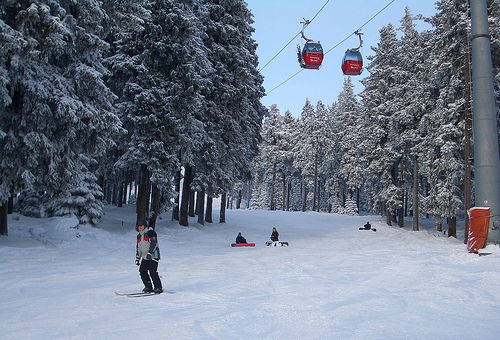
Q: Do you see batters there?
A: No, there are no batters.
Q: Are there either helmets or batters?
A: No, there are no batters or helmets.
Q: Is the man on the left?
A: Yes, the man is on the left of the image.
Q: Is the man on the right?
A: No, the man is on the left of the image.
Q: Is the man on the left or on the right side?
A: The man is on the left of the image.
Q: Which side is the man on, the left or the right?
A: The man is on the left of the image.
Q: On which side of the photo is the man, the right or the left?
A: The man is on the left of the image.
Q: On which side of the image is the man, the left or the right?
A: The man is on the left of the image.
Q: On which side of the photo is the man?
A: The man is on the left of the image.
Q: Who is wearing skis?
A: The man is wearing skis.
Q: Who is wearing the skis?
A: The man is wearing skis.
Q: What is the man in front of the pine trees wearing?
A: The man is wearing skis.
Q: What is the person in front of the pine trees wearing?
A: The man is wearing skis.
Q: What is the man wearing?
A: The man is wearing skis.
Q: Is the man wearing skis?
A: Yes, the man is wearing skis.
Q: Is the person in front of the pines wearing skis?
A: Yes, the man is wearing skis.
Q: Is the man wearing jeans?
A: No, the man is wearing skis.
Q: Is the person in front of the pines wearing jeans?
A: No, the man is wearing skis.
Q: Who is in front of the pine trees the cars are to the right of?
A: The man is in front of the pines.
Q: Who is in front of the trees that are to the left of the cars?
A: The man is in front of the pines.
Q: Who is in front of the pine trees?
A: The man is in front of the pines.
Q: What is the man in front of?
A: The man is in front of the pines.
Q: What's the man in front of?
A: The man is in front of the pines.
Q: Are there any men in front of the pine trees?
A: Yes, there is a man in front of the pine trees.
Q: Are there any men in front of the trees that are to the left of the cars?
A: Yes, there is a man in front of the pine trees.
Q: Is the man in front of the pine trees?
A: Yes, the man is in front of the pine trees.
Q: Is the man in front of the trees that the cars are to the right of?
A: Yes, the man is in front of the pine trees.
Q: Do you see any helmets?
A: No, there are no helmets.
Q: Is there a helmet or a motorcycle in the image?
A: No, there are no helmets or motorcycles.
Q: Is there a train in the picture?
A: No, there are no trains.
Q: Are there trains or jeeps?
A: No, there are no trains or jeeps.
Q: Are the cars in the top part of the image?
A: Yes, the cars are in the top of the image.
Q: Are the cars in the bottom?
A: No, the cars are in the top of the image.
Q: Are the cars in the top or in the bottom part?
A: The cars are in the top of the image.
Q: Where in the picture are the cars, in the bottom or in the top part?
A: The cars are in the top of the image.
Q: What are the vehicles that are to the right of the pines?
A: The vehicles are cars.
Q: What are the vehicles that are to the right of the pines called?
A: The vehicles are cars.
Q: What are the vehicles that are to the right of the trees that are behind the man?
A: The vehicles are cars.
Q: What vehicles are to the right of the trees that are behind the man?
A: The vehicles are cars.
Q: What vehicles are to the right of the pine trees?
A: The vehicles are cars.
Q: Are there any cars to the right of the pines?
A: Yes, there are cars to the right of the pines.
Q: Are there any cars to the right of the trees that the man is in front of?
A: Yes, there are cars to the right of the pines.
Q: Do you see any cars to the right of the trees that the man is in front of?
A: Yes, there are cars to the right of the pines.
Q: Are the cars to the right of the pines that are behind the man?
A: Yes, the cars are to the right of the pines.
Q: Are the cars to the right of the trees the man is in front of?
A: Yes, the cars are to the right of the pines.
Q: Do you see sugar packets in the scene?
A: No, there are no sugar packets.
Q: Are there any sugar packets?
A: No, there are no sugar packets.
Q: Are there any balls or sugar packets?
A: No, there are no sugar packets or balls.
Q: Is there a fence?
A: No, there are no fences.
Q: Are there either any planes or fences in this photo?
A: No, there are no fences or planes.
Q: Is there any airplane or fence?
A: No, there are no fences or airplanes.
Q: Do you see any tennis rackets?
A: No, there are no tennis rackets.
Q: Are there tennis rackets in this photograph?
A: No, there are no tennis rackets.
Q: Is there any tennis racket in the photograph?
A: No, there are no rackets.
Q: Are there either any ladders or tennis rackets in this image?
A: No, there are no tennis rackets or ladders.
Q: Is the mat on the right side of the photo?
A: Yes, the mat is on the right of the image.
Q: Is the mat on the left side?
A: No, the mat is on the right of the image.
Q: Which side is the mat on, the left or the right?
A: The mat is on the right of the image.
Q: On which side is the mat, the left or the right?
A: The mat is on the right of the image.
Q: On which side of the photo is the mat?
A: The mat is on the right of the image.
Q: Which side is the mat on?
A: The mat is on the right of the image.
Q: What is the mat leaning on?
A: The mat is leaning on the pole.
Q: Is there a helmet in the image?
A: No, there are no helmets.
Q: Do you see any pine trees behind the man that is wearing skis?
A: Yes, there are pine trees behind the man.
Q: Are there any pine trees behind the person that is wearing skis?
A: Yes, there are pine trees behind the man.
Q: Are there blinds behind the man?
A: No, there are pine trees behind the man.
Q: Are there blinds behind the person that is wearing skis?
A: No, there are pine trees behind the man.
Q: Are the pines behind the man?
A: Yes, the pines are behind the man.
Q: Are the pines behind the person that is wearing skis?
A: Yes, the pines are behind the man.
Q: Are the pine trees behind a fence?
A: No, the pine trees are behind the man.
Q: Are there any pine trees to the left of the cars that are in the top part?
A: Yes, there are pine trees to the left of the cars.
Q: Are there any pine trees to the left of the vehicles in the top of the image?
A: Yes, there are pine trees to the left of the cars.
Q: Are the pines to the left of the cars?
A: Yes, the pines are to the left of the cars.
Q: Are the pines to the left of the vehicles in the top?
A: Yes, the pines are to the left of the cars.